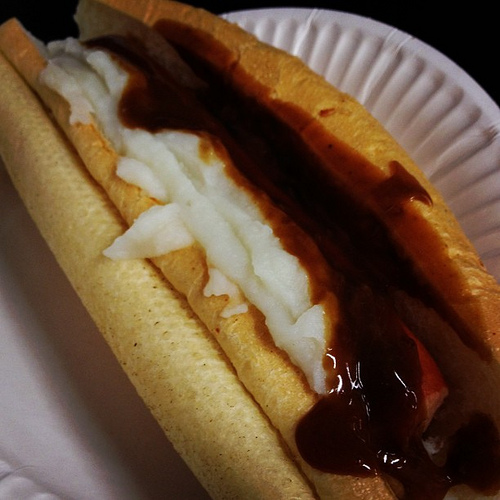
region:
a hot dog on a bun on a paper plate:
[25, 20, 492, 482]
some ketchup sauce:
[340, 345, 411, 440]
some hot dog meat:
[410, 340, 442, 425]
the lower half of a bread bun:
[182, 355, 297, 492]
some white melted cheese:
[160, 185, 295, 325]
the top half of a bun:
[295, 70, 370, 146]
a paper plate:
[395, 58, 469, 115]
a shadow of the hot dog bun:
[22, 276, 62, 333]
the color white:
[4, 380, 50, 462]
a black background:
[438, 5, 490, 40]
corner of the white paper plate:
[215, 3, 498, 293]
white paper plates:
[4, 3, 486, 493]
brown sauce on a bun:
[375, 149, 440, 236]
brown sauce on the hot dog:
[140, 20, 494, 494]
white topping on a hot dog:
[33, 28, 374, 425]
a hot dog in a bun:
[50, 21, 441, 425]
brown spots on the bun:
[109, 292, 209, 452]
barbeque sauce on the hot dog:
[386, 343, 466, 420]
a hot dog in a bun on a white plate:
[4, 5, 493, 498]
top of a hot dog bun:
[134, 1, 499, 327]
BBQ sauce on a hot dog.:
[86, 15, 434, 499]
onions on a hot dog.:
[29, 20, 336, 402]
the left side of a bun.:
[69, 0, 497, 423]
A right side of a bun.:
[0, 8, 404, 498]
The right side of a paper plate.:
[207, 0, 497, 287]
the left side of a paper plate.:
[1, 160, 213, 493]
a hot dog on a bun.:
[57, 23, 452, 437]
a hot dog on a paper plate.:
[1, 6, 498, 498]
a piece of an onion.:
[95, 200, 205, 273]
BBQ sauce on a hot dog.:
[252, 175, 377, 236]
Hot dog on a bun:
[3, 40, 481, 497]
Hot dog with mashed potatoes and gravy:
[3, 35, 468, 495]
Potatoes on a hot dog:
[71, 65, 247, 247]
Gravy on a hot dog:
[183, 58, 328, 216]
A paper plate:
[264, 36, 488, 170]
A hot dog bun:
[2, 45, 183, 362]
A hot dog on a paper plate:
[17, 40, 492, 447]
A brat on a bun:
[128, 58, 479, 472]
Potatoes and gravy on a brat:
[50, 49, 466, 452]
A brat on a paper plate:
[5, 38, 480, 499]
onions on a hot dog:
[123, 143, 300, 304]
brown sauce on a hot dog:
[312, 168, 399, 468]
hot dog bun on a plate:
[17, 160, 252, 421]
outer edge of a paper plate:
[232, 0, 493, 250]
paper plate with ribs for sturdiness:
[242, 1, 485, 211]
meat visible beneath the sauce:
[403, 328, 450, 417]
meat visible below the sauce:
[400, 317, 448, 430]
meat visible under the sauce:
[397, 313, 452, 442]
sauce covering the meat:
[349, 244, 482, 466]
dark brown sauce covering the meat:
[323, 205, 480, 465]